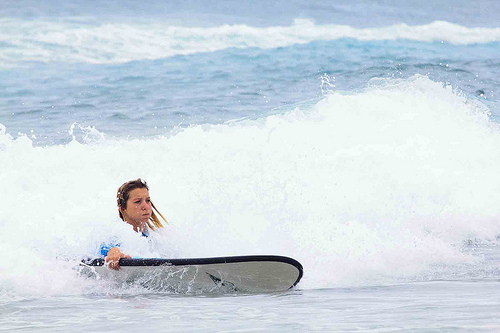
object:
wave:
[0, 67, 500, 299]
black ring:
[88, 252, 305, 291]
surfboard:
[80, 255, 304, 295]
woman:
[84, 177, 189, 264]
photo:
[0, 0, 500, 333]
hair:
[116, 177, 166, 232]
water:
[0, 0, 500, 330]